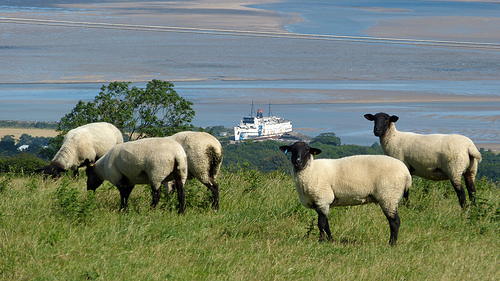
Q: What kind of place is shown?
A: It is a field.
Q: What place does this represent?
A: It represents the field.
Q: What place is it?
A: It is a field.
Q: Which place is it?
A: It is a field.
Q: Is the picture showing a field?
A: Yes, it is showing a field.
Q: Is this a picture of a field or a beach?
A: It is showing a field.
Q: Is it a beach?
A: No, it is a field.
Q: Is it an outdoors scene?
A: Yes, it is outdoors.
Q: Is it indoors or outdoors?
A: It is outdoors.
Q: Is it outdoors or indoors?
A: It is outdoors.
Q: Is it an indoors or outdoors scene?
A: It is outdoors.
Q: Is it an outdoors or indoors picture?
A: It is outdoors.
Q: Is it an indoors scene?
A: No, it is outdoors.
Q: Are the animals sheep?
A: Yes, all the animals are sheep.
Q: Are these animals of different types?
A: No, all the animals are sheep.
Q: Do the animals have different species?
A: No, all the animals are sheep.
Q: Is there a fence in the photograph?
A: No, there are no fences.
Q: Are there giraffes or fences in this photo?
A: No, there are no fences or giraffes.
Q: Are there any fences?
A: No, there are no fences.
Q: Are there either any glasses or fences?
A: No, there are no fences or glasses.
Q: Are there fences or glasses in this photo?
A: No, there are no fences or glasses.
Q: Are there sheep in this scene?
A: Yes, there is a sheep.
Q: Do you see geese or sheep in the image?
A: Yes, there is a sheep.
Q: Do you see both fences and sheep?
A: No, there is a sheep but no fences.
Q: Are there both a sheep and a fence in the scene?
A: No, there is a sheep but no fences.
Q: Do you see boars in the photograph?
A: No, there are no boars.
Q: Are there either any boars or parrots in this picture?
A: No, there are no boars or parrots.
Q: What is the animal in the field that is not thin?
A: The animal is a sheep.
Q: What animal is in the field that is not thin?
A: The animal is a sheep.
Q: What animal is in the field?
A: The animal is a sheep.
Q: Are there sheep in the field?
A: Yes, there is a sheep in the field.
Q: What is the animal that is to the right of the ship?
A: The animal is a sheep.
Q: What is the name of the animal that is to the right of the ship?
A: The animal is a sheep.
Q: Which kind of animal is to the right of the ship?
A: The animal is a sheep.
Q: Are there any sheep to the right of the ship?
A: Yes, there is a sheep to the right of the ship.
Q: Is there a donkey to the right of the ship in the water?
A: No, there is a sheep to the right of the ship.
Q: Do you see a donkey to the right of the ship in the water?
A: No, there is a sheep to the right of the ship.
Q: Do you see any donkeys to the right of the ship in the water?
A: No, there is a sheep to the right of the ship.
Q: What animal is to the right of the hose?
A: The animal is a sheep.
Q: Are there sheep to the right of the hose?
A: Yes, there is a sheep to the right of the hose.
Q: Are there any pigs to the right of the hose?
A: No, there is a sheep to the right of the hose.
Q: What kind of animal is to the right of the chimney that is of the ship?
A: The animal is a sheep.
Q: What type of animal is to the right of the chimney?
A: The animal is a sheep.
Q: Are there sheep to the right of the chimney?
A: Yes, there is a sheep to the right of the chimney.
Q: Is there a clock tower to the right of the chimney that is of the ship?
A: No, there is a sheep to the right of the chimney.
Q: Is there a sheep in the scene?
A: Yes, there is a sheep.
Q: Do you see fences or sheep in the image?
A: Yes, there is a sheep.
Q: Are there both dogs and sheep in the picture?
A: No, there is a sheep but no dogs.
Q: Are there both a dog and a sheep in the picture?
A: No, there is a sheep but no dogs.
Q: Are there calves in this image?
A: No, there are no calves.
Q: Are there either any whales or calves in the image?
A: No, there are no calves or whales.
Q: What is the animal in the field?
A: The animal is a sheep.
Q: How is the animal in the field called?
A: The animal is a sheep.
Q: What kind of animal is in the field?
A: The animal is a sheep.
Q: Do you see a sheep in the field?
A: Yes, there is a sheep in the field.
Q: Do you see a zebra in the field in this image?
A: No, there is a sheep in the field.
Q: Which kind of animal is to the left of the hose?
A: The animal is a sheep.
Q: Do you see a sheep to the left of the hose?
A: Yes, there is a sheep to the left of the hose.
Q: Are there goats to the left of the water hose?
A: No, there is a sheep to the left of the water hose.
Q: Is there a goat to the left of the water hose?
A: No, there is a sheep to the left of the water hose.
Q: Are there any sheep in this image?
A: Yes, there is a sheep.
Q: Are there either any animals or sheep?
A: Yes, there is a sheep.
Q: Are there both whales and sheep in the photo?
A: No, there is a sheep but no whales.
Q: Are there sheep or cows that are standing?
A: Yes, the sheep is standing.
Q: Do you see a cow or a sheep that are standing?
A: Yes, the sheep is standing.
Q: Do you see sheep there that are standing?
A: Yes, there is a sheep that is standing.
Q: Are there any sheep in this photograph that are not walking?
A: Yes, there is a sheep that is standing.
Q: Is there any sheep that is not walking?
A: Yes, there is a sheep that is standing.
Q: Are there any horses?
A: No, there are no horses.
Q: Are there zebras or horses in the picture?
A: No, there are no horses or zebras.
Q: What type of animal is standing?
A: The animal is a sheep.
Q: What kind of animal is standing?
A: The animal is a sheep.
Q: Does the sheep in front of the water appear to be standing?
A: Yes, the sheep is standing.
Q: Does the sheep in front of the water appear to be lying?
A: No, the sheep is standing.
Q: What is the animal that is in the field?
A: The animal is a sheep.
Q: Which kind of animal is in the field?
A: The animal is a sheep.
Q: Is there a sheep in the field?
A: Yes, there is a sheep in the field.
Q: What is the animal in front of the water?
A: The animal is a sheep.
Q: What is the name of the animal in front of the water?
A: The animal is a sheep.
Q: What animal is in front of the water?
A: The animal is a sheep.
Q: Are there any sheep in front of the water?
A: Yes, there is a sheep in front of the water.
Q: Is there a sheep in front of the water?
A: Yes, there is a sheep in front of the water.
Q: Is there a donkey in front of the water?
A: No, there is a sheep in front of the water.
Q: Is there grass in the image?
A: Yes, there is grass.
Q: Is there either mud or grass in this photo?
A: Yes, there is grass.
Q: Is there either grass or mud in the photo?
A: Yes, there is grass.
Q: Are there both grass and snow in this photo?
A: No, there is grass but no snow.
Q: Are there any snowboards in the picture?
A: No, there are no snowboards.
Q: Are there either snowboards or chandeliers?
A: No, there are no snowboards or chandeliers.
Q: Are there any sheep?
A: Yes, there is a sheep.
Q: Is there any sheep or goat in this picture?
A: Yes, there is a sheep.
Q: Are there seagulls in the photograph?
A: No, there are no seagulls.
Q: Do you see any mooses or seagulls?
A: No, there are no seagulls or mooses.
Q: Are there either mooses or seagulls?
A: No, there are no seagulls or mooses.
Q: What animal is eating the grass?
A: The sheep is eating the grass.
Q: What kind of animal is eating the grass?
A: The animal is a sheep.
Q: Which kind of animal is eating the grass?
A: The animal is a sheep.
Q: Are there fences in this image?
A: No, there are no fences.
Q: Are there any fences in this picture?
A: No, there are no fences.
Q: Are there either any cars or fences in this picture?
A: No, there are no fences or cars.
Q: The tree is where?
A: The tree is on the field.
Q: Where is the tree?
A: The tree is on the field.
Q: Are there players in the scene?
A: No, there are no players.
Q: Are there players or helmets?
A: No, there are no players or helmets.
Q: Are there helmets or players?
A: No, there are no players or helmets.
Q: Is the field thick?
A: Yes, the field is thick.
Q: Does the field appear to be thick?
A: Yes, the field is thick.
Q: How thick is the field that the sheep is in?
A: The field is thick.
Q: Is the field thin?
A: No, the field is thick.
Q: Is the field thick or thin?
A: The field is thick.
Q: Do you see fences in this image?
A: No, there are no fences.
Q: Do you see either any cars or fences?
A: No, there are no fences or cars.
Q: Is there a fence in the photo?
A: No, there are no fences.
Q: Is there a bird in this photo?
A: No, there are no birds.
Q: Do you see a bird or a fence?
A: No, there are no birds or fences.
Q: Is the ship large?
A: Yes, the ship is large.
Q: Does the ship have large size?
A: Yes, the ship is large.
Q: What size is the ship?
A: The ship is large.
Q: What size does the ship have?
A: The ship has large size.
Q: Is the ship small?
A: No, the ship is large.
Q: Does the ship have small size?
A: No, the ship is large.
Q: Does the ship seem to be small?
A: No, the ship is large.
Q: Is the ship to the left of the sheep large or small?
A: The ship is large.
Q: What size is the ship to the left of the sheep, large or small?
A: The ship is large.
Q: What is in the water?
A: The ship is in the water.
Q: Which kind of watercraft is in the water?
A: The watercraft is a ship.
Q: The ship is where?
A: The ship is in the water.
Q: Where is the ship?
A: The ship is in the water.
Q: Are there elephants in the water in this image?
A: No, there is a ship in the water.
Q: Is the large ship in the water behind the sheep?
A: Yes, the ship is in the water.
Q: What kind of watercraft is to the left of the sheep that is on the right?
A: The watercraft is a ship.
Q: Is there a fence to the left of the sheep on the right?
A: No, there is a ship to the left of the sheep.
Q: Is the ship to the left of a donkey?
A: No, the ship is to the left of a sheep.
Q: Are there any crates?
A: No, there are no crates.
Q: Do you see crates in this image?
A: No, there are no crates.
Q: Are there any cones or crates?
A: No, there are no crates or cones.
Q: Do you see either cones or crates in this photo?
A: No, there are no crates or cones.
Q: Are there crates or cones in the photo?
A: No, there are no crates or cones.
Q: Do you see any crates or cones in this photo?
A: No, there are no crates or cones.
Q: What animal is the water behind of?
A: The water is behind the sheep.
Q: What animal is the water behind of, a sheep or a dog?
A: The water is behind a sheep.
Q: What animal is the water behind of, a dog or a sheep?
A: The water is behind a sheep.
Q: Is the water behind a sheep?
A: Yes, the water is behind a sheep.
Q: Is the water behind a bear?
A: No, the water is behind a sheep.